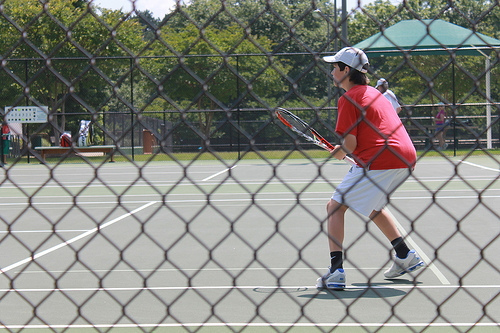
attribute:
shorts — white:
[337, 159, 408, 212]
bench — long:
[34, 142, 115, 162]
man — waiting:
[317, 46, 424, 291]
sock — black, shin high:
[322, 229, 366, 279]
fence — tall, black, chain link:
[4, 8, 484, 331]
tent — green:
[350, 18, 498, 148]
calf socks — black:
[312, 241, 368, 278]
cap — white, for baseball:
[321, 45, 370, 74]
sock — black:
[390, 239, 411, 251]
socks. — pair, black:
[325, 237, 412, 267]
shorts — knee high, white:
[330, 165, 363, 191]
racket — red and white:
[258, 93, 342, 170]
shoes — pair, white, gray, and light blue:
[283, 260, 443, 297]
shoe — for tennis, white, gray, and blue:
[316, 267, 351, 297]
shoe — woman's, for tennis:
[375, 248, 431, 283]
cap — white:
[318, 46, 372, 79]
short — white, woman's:
[323, 143, 421, 230]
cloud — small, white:
[145, 2, 180, 16]